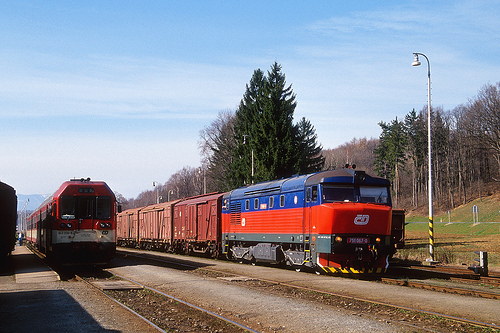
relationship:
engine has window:
[219, 161, 399, 278] [242, 197, 252, 212]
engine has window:
[219, 161, 399, 278] [253, 197, 260, 210]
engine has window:
[219, 161, 399, 278] [267, 194, 276, 210]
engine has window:
[219, 161, 399, 278] [277, 193, 287, 208]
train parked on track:
[116, 161, 395, 279] [372, 257, 498, 307]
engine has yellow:
[219, 161, 399, 278] [318, 262, 391, 277]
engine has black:
[219, 161, 399, 278] [322, 264, 389, 274]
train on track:
[116, 161, 395, 279] [372, 257, 498, 307]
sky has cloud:
[1, 1, 498, 160] [4, 63, 202, 117]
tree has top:
[217, 57, 321, 180] [263, 61, 284, 89]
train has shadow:
[116, 161, 395, 279] [383, 262, 485, 285]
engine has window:
[219, 161, 399, 278] [320, 182, 395, 205]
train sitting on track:
[116, 161, 395, 279] [372, 257, 498, 307]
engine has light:
[219, 161, 399, 278] [332, 232, 344, 244]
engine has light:
[219, 161, 399, 278] [374, 236, 383, 246]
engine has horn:
[219, 161, 399, 278] [341, 160, 362, 170]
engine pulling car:
[219, 161, 399, 278] [170, 192, 222, 248]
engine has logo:
[219, 161, 399, 278] [351, 211, 373, 227]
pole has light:
[409, 50, 446, 272] [410, 49, 421, 68]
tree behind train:
[217, 57, 321, 180] [116, 161, 395, 279]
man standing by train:
[17, 226, 26, 247] [22, 173, 121, 256]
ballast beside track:
[402, 269, 497, 288] [372, 257, 498, 307]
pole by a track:
[409, 50, 446, 272] [22, 239, 497, 327]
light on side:
[410, 49, 421, 68] [410, 53, 430, 263]